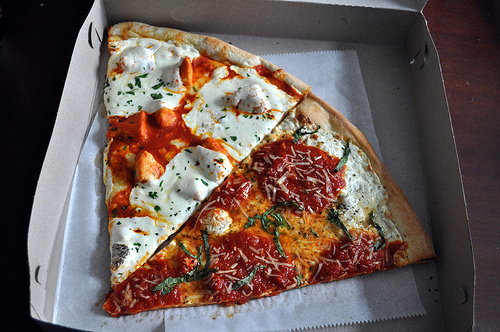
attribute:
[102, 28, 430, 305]
pizza — sliced, cheese , slice , pepperoni , red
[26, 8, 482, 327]
box — cardboard 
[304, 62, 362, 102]
paper — wax , piece 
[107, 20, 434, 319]
pizze — two slices 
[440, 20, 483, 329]
table — wooden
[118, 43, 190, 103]
cheese — globs 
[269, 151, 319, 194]
cheese — sprinkles , extra 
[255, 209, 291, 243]
parsley — shredded 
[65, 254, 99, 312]
tissue — white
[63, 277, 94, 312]
tissue — white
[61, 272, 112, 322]
tissue — white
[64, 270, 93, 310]
tissue — white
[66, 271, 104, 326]
tissue — white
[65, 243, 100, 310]
tissue — white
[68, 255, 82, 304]
tissue — white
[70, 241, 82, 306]
tissue — white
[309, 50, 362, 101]
tissue — white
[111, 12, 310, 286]
slices — pizza 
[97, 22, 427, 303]
slices — different toppings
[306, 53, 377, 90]
paper — white 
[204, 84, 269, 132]
cheese —  melted white , large blobs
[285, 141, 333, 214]
sauce — tomato , white shreds, green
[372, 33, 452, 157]
box — cardboard 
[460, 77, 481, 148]
surface — dark brown 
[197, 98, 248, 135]
cheese — puffy white bubble , edge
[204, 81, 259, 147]
cheese — melted 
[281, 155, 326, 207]
sauce — tomato  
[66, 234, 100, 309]
paper — wrinkles, serrated edge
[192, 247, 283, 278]
ingredient — pebble-like 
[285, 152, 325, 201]
sauce — tomato 